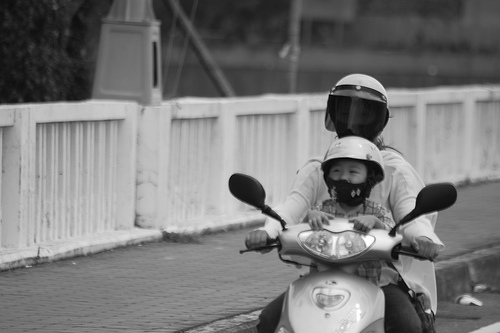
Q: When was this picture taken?
A: Day time.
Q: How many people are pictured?
A: Two.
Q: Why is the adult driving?
A: The child is too young.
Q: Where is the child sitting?
A: In front of the adult.